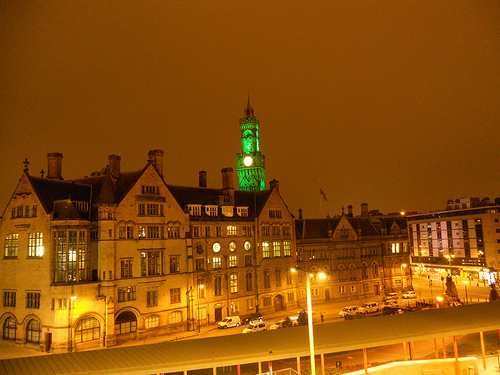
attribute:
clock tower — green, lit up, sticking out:
[235, 103, 270, 203]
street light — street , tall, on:
[285, 257, 323, 362]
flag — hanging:
[315, 188, 339, 203]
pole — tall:
[316, 185, 329, 218]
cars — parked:
[213, 286, 405, 328]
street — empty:
[165, 268, 426, 345]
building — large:
[35, 140, 493, 370]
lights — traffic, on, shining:
[156, 241, 497, 281]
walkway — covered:
[140, 310, 488, 364]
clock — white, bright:
[243, 154, 256, 167]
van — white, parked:
[219, 313, 235, 330]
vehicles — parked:
[194, 288, 400, 341]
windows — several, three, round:
[223, 236, 304, 276]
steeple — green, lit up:
[235, 108, 266, 158]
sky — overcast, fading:
[8, 7, 469, 204]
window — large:
[28, 236, 49, 265]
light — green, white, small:
[237, 115, 267, 190]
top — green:
[182, 99, 265, 184]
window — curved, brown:
[107, 312, 136, 331]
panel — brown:
[33, 295, 494, 371]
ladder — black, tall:
[492, 216, 500, 260]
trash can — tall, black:
[331, 360, 347, 373]